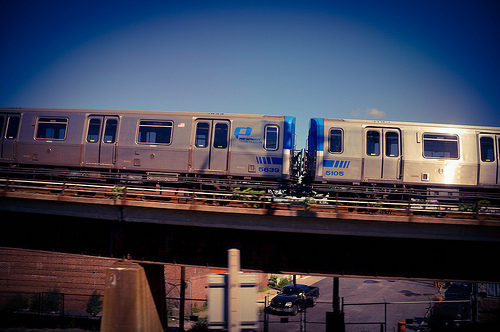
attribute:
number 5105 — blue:
[325, 169, 347, 178]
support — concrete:
[97, 257, 167, 329]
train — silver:
[6, 92, 494, 212]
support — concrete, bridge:
[101, 260, 167, 330]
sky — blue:
[2, 0, 496, 142]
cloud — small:
[146, 24, 268, 85]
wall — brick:
[36, 248, 155, 310]